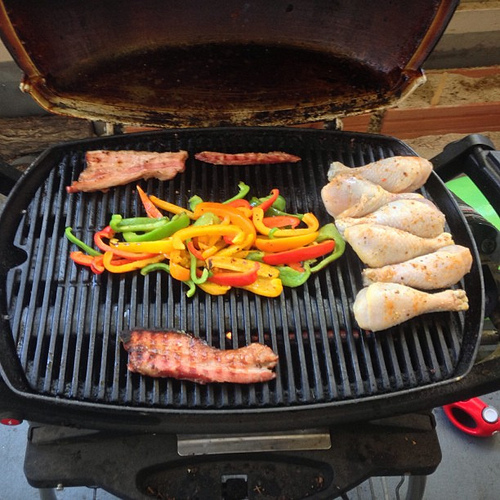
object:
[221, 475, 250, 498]
knob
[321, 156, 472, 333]
legs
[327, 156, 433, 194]
chicken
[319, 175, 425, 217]
chicken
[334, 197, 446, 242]
chicken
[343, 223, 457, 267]
chicken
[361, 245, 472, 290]
chicken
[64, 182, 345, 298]
peppers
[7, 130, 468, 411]
grill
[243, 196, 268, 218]
ground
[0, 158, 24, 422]
grill handle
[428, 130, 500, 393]
grill handle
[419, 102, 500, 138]
step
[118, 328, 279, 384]
rib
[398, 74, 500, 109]
dirt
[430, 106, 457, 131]
ground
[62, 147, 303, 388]
grilled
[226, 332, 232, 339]
flame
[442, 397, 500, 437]
red item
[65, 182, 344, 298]
food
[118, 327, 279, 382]
ugrilling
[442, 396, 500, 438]
lighter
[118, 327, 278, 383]
meat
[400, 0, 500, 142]
steps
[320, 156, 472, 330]
meat